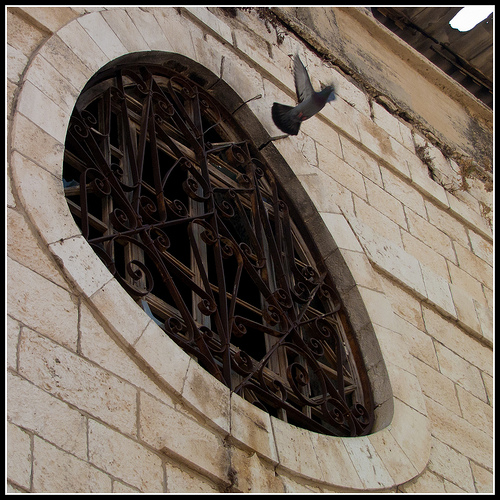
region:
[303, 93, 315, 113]
A pigeon in the air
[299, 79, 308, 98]
A pigeon flying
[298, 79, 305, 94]
The wing of a pigeon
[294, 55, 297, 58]
The tip of the wing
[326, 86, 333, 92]
The head of the pigeon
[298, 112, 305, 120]
The legs are retracted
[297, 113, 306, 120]
Red color on the legs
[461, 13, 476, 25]
A hole in the roof tile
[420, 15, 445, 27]
The roof tiles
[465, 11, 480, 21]
The sky through a tile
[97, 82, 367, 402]
A open metal window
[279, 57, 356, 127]
A bird flying away from the window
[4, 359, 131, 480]
A white brick house wall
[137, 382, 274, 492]
A white brick house wall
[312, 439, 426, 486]
A white brick house wall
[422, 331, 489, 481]
A white brick house wall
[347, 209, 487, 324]
A white brick house wall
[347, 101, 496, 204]
A white brick house wall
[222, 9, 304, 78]
A white brick house wall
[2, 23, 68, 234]
A white brick house wall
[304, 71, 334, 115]
bird is in air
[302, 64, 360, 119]
bird has black head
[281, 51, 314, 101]
black and grey wings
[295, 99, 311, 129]
bird has orange feet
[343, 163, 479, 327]
light brown bricks on building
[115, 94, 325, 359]
dark brown bars for window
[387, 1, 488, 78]
tan roof on building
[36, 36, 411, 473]
building is light brown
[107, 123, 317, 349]
A window on the photo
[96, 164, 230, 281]
Wooden bar on the window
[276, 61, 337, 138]
A bird flying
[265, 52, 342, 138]
A bird in the air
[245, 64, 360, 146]
Black and gray bird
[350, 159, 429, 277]
Stones in the wall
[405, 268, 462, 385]
Stone wall in the building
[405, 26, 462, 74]
Ceiling in the building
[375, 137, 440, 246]
Wall made of stones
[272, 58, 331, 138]
bird on the side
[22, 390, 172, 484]
bricks on the building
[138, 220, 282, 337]
gate on the window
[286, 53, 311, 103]
wing of the bird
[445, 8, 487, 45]
open part of roof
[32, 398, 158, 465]
the wall is tan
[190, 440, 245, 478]
dirty marks on the wall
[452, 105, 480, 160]
dirty part on wall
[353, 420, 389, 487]
lighter part on wall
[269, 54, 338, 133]
the bird is in mid air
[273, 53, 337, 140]
the bird is flapping his wings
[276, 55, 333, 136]
the bird is of the pigeon type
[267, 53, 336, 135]
the bird has grey tones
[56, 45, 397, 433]
the window is round in shape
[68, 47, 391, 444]
the window has a metal grate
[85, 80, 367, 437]
door are behind the grate